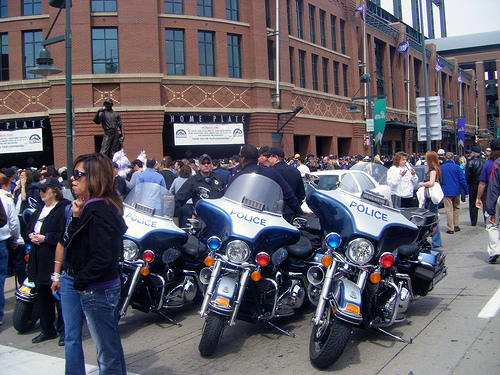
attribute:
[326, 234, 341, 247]
light — blue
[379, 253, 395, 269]
light — red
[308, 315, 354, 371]
tire — rubber, here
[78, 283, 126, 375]
jeans — blue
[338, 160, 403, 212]
windshield — here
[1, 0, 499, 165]
wall — brick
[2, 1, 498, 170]
building — huge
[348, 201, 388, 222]
police — written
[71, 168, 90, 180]
sunglasses — being worn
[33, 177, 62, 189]
cap — blue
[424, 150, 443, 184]
hair — blond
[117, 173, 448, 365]
bikes — parked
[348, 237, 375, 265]
headlight — here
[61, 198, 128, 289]
hoodie — black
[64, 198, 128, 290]
jacket — blue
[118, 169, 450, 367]
motorcycles — parked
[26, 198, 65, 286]
jacket — black